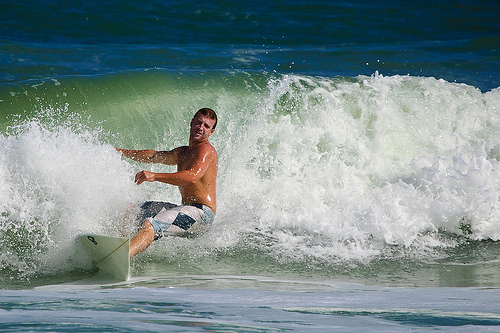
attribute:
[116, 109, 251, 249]
man — surfing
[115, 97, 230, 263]
man — brown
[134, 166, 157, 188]
hand — in front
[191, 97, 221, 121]
hair — short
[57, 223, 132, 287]
surfboard — white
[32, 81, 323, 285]
wave — splashing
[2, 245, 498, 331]
water — calm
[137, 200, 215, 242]
short — blue, gray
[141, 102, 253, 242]
surfer — bend backward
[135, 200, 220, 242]
shorts — blue, white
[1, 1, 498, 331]
water — choppy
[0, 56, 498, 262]
wave — big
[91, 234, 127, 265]
stripe — gold, on the bottom